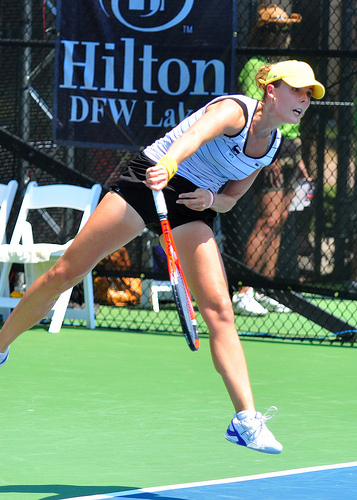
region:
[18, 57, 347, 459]
A woman playing tennis.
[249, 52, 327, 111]
Yellow cap on woman's head.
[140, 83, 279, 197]
A striped tank top.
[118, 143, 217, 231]
A pair of black shorts.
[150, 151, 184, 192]
A yellow band around right wrist.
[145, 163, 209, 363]
Tennis raquet in right hand.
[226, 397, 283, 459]
A white tennis shoe.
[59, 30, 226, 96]
The word Hilton in large white letters.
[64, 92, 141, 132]
The letters DFW in large white letters.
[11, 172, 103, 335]
A white chair.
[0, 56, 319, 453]
Lady jumping to serve in tennis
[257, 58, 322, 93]
Yellow cap on lady tennis player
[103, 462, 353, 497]
Small part of blue tennis court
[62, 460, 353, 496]
Small part of white baseline of tennis court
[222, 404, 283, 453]
White and purple shoe of lady tennis player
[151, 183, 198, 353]
Orange racket used by lady tennis player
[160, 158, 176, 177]
Yellow wristband on lady tennis player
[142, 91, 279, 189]
White, black striped shirt on lady tennis player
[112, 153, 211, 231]
Black shorts on lady tennis player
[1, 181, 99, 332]
White chair on tennis court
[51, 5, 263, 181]
hilton sign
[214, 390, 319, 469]
athletic sneakers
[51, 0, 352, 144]
hilton sign on a fence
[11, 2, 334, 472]
a metal fence around a tennis court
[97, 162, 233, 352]
a tennis racket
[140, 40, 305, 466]
a woman wearing athletic sneakers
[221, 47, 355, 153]
a woman wearing a hat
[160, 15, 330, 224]
a woman wearing a striped tank top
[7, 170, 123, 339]
a white folding chair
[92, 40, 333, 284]
a woman wearing black shorts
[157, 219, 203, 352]
a red and black hockey stick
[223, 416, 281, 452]
blue and white sneakers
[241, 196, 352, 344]
black wire mesh on the sides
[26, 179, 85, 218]
a white chair on the sidewalk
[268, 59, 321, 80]
a yellow cap on the woman's head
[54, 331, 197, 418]
a spotless green lawn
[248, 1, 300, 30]
an orange cap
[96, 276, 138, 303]
an orange object on the ground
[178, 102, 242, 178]
a stripped vest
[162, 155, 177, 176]
a yellow hand band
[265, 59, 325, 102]
woman wearing yellow cap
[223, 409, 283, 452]
woman wearing white tennis shoes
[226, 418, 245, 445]
blue design on shoe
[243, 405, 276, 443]
white shoelaces on shoe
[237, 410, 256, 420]
woman wearing white sock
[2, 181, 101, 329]
white wooden folding chair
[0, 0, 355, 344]
black fence behind woman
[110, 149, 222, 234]
woman wearing black shorts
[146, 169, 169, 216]
handle of tennis racquet is white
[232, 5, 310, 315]
person standing behind fence